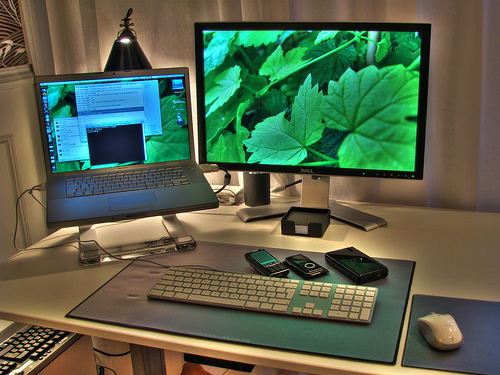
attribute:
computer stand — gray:
[66, 218, 205, 268]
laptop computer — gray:
[29, 66, 219, 230]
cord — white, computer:
[11, 176, 42, 256]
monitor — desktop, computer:
[193, 20, 434, 230]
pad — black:
[386, 282, 498, 367]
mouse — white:
[391, 289, 495, 374]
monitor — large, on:
[194, 22, 433, 209]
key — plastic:
[299, 287, 310, 299]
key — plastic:
[303, 301, 315, 311]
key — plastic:
[311, 308, 325, 318]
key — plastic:
[301, 308, 313, 318]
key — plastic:
[289, 305, 306, 316]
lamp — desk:
[98, 23, 155, 71]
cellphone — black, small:
[245, 246, 290, 278]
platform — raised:
[68, 209, 195, 261]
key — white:
[268, 295, 293, 304]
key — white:
[255, 289, 270, 300]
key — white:
[228, 280, 237, 290]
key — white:
[198, 284, 212, 294]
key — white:
[283, 283, 294, 288]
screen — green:
[254, 247, 275, 267]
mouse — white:
[418, 309, 465, 350]